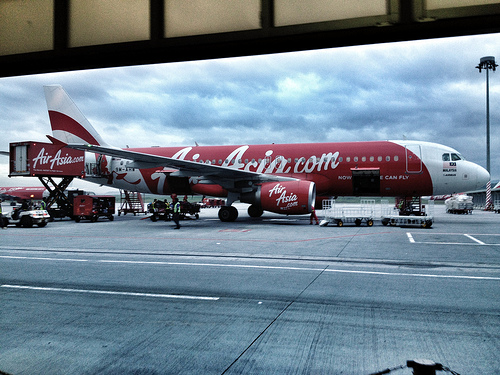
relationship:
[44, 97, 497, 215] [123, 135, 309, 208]
plane has wing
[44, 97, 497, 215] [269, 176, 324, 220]
plane has engine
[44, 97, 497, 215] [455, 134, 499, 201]
plane has nose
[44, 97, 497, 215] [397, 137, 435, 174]
plane has door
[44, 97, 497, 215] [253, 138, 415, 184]
plane has windows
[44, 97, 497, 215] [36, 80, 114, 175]
plane has tail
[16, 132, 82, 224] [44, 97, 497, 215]
lift near plane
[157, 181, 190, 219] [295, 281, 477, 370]
man on pavement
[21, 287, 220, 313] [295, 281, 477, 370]
line on pavement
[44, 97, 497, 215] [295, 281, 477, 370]
plane on pavement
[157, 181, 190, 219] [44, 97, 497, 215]
man next to plane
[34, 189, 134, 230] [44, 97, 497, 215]
cart near plane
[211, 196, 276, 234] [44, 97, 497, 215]
wheels under plane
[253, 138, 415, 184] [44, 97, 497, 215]
windows on plane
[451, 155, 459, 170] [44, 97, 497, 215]
windshield on plane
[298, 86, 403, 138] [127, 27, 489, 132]
clouds in sky